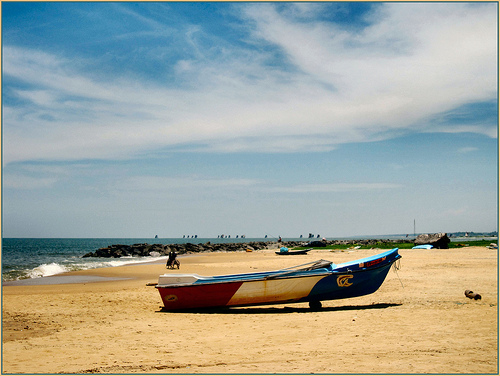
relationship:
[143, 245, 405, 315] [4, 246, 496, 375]
boat on beach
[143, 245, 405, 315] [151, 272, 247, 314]
boat has red stern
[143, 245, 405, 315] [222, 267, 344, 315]
boat has white beam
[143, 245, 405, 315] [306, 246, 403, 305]
boat has blue bow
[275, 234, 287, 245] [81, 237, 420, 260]
person sits on breakwater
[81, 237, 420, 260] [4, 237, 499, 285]
breakwater in water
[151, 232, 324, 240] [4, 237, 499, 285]
boats in water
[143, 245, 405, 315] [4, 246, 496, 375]
boat on sand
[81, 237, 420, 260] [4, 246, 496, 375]
breakwater near sand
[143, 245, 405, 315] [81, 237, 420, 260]
boat near breakwater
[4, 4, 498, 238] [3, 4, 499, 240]
sky has clouds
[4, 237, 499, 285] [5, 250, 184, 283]
water has waves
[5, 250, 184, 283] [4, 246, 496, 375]
waves near sand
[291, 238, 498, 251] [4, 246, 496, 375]
grass near sand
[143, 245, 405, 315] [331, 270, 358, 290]
boat has logo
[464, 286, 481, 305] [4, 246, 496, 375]
log on sand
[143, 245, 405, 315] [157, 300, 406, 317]
boat has shadow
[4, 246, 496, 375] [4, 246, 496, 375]
beach has sand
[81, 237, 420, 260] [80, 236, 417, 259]
breakwater has rocks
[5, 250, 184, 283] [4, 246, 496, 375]
waves near beach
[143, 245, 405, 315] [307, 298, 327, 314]
boat on log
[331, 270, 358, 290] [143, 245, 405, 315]
logo on boat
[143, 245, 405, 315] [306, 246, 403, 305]
boat has bow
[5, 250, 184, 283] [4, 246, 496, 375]
waves on sand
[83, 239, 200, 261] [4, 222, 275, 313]
rocks are in jetty